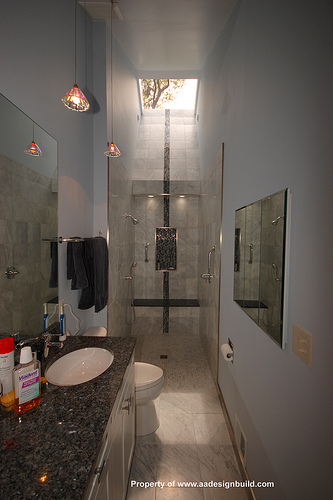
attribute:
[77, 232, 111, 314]
towel — black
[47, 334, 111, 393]
sink — oval, white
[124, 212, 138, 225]
shower head — stainless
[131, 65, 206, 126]
skylight — open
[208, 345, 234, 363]
paper — white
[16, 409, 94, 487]
counter — granite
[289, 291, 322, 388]
air vent — white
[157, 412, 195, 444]
tile — floor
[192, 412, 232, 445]
tile — floor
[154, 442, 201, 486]
tile — floor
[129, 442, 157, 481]
tile — floor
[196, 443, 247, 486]
tile — floor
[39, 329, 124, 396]
sink — white, oval, porcelain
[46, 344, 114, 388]
sink — porcelain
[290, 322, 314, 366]
switch — beige, electrical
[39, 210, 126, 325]
towels — dark, gray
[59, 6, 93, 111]
lamp — hanging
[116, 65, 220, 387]
shower stall — enclosed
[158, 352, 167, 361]
drain — square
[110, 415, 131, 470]
cabinet doors — white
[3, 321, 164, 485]
counter top — black, granite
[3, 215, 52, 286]
mirror hanging — large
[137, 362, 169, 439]
toilet — white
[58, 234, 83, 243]
towel rack — bath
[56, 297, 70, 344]
toothbrush — electric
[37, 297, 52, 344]
toothbrush — electric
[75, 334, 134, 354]
grey counter — black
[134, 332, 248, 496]
floor — gray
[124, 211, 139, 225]
shower head — silver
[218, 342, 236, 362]
toilet paper — white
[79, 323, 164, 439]
toilet — white, porcelain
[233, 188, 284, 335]
mirror — large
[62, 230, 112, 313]
towels — black, fluffy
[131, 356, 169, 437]
toilet — white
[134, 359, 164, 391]
toilet seat — down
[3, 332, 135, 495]
vanity top — granite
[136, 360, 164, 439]
toilet — white, ceramic